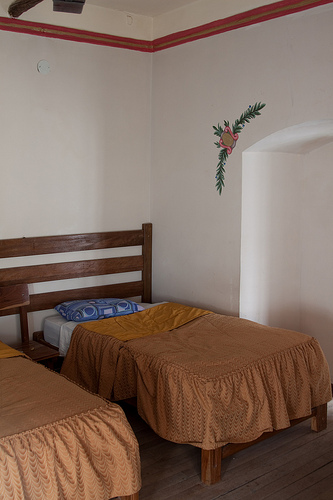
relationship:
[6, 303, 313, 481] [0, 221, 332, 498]
sheets on beds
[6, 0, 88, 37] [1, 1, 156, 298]
wood on wall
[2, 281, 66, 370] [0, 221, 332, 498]
chair between beds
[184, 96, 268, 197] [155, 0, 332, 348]
decoration on walls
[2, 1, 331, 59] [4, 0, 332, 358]
boarder on walls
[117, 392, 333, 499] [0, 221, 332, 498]
legs on beds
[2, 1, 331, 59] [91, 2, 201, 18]
boarder near ceiling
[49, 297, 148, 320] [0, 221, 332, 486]
pillow on beds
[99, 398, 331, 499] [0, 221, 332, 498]
floor beneath beds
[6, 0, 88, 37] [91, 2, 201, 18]
wood on ceiling